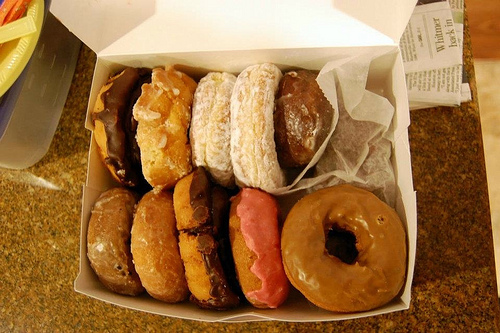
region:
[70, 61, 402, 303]
doughnuts in a box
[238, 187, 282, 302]
this doughnut has pink frosting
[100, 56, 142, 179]
this doughnut has chocolate frosting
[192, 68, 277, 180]
these doughnuts are sugar-coated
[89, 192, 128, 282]
this doughnut is glazed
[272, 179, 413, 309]
this doughnut has brown frosting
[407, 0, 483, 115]
newspapers beside the box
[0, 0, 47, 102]
a yellow plate by the box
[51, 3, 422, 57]
the box is white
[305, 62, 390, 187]
paper in the doughnut box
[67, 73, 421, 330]
donuts in the box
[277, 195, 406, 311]
the frosting is brown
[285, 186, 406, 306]
dough nut in a box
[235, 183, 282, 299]
dough nut in a box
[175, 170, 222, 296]
dough nut in a box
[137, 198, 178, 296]
dough nut in a box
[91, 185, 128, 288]
dough nut in a box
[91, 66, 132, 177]
dough nut in a box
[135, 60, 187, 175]
dough nut in a box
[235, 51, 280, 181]
dough nut in a box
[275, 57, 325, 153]
dough nut in a box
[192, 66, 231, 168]
dough nut in a box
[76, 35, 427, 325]
A box of assorted doughnuts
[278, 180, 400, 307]
This doughnut has maple frosting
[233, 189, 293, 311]
This doughnut has pink frosting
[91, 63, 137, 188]
This doughnut has chocolate frosting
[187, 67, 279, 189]
These doughnuts are coated in powdered sugar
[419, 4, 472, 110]
This is a newspaper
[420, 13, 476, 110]
The newspaper is folded in half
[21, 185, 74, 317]
The tabletop is brown granite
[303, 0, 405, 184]
White tissue paper in the box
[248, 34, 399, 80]
The box is made of cardboard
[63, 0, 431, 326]
donut box missing donut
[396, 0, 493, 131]
bottom corners of two newspapers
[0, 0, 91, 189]
plastic food bucket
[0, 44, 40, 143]
plastic food bucket is transparent, has measurement lines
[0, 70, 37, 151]
blue plastic cover of clear plastic bucket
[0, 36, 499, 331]
a granite countertop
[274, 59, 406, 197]
crumpled up tissue beneath ex-donut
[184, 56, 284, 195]
two plain donuts topped w/ powder/icing/confectioner's sugar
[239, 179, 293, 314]
pink, strawberryesque frosting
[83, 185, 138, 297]
dark glazed donut, singular